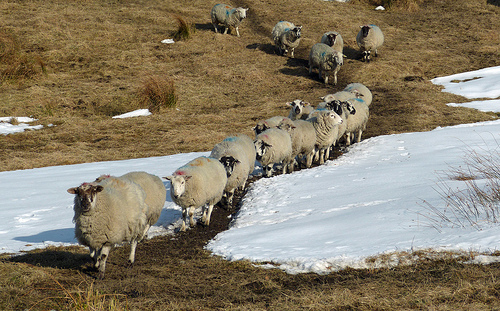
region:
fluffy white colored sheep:
[65, 173, 140, 273]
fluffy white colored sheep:
[93, 167, 158, 243]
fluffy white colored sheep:
[164, 156, 224, 233]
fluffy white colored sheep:
[206, 134, 253, 219]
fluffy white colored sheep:
[248, 128, 288, 176]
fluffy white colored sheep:
[247, 110, 282, 133]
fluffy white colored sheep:
[282, 117, 311, 172]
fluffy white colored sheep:
[310, 105, 335, 167]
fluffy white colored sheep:
[286, 100, 310, 123]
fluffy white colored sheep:
[307, 42, 342, 89]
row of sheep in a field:
[70, 80, 374, 273]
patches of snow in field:
[205, 119, 498, 271]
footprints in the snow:
[247, 178, 391, 220]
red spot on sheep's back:
[171, 165, 188, 177]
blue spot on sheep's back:
[222, 135, 238, 144]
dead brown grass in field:
[9, 4, 491, 309]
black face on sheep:
[219, 155, 239, 177]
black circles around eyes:
[290, 98, 303, 115]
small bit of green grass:
[152, 88, 183, 110]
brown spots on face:
[75, 183, 93, 195]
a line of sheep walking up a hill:
[68, 5, 380, 275]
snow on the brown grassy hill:
[2, 68, 499, 273]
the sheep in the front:
[70, 170, 166, 272]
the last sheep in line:
[210, 1, 247, 34]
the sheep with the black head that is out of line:
[356, 25, 383, 59]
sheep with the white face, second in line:
[164, 155, 224, 234]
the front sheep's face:
[68, 183, 100, 213]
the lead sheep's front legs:
[90, 247, 108, 272]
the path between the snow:
[165, 146, 348, 242]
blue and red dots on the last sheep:
[224, 4, 236, 18]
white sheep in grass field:
[74, 171, 137, 260]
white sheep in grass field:
[138, 162, 180, 205]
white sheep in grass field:
[177, 144, 219, 223]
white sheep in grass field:
[223, 134, 255, 187]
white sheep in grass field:
[255, 118, 284, 176]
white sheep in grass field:
[287, 112, 310, 153]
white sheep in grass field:
[322, 111, 336, 156]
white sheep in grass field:
[344, 95, 376, 135]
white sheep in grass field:
[312, 43, 342, 76]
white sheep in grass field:
[356, 25, 391, 60]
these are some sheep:
[87, 89, 339, 208]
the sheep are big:
[193, 153, 248, 205]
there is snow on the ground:
[247, 135, 424, 296]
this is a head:
[79, 192, 96, 207]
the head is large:
[61, 166, 109, 198]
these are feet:
[80, 264, 162, 291]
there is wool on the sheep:
[98, 199, 164, 246]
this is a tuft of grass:
[94, 68, 196, 188]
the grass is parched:
[163, 278, 311, 301]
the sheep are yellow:
[120, 189, 180, 276]